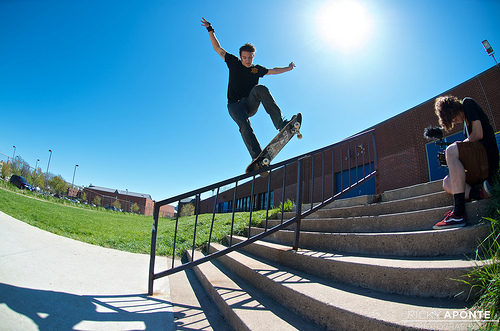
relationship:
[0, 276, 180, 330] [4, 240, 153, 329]
shadow on ground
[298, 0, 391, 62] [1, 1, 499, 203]
sun shining in sky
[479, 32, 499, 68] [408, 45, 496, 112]
lamp on roof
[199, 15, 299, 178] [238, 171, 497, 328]
guy sitting on staircase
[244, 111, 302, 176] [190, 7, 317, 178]
skate board under guy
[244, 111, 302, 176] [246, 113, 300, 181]
skate board under feet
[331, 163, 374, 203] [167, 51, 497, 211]
window on side building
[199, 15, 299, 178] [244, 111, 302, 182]
guy on skate board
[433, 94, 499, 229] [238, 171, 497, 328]
boy sitting on staircase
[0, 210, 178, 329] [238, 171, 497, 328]
sidewalk leads up to staircase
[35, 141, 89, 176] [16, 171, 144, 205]
lights in lot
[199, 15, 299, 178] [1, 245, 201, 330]
guy on sidewalk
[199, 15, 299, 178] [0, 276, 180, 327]
guy has shadow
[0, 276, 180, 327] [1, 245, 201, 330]
shadow on sidewalk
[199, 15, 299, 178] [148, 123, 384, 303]
guy sliding down rail